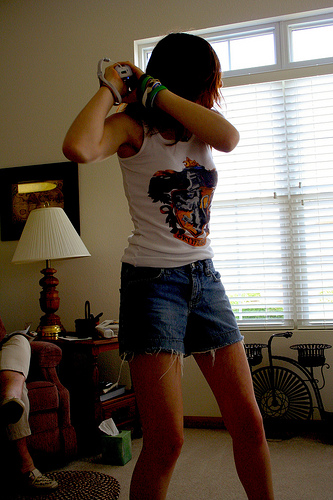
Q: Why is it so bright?
A: Sunny.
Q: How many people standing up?
A: One.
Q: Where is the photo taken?
A: The living room.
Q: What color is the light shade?
A: White.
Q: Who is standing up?
A: The woman.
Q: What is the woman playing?
A: Video game.